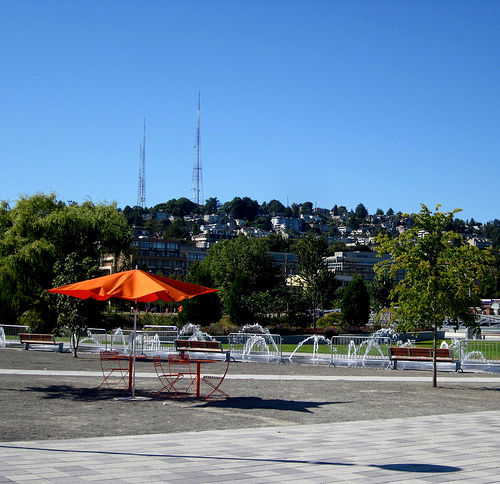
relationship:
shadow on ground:
[2, 444, 462, 474] [0, 349, 498, 481]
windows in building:
[133, 237, 183, 249] [122, 235, 188, 282]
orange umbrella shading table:
[46, 264, 219, 393] [99, 349, 230, 404]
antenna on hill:
[190, 85, 205, 210] [2, 190, 497, 342]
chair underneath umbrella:
[98, 348, 132, 392] [47, 271, 220, 353]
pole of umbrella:
[128, 302, 138, 399] [46, 268, 213, 303]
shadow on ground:
[190, 396, 354, 414] [0, 349, 498, 481]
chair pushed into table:
[83, 316, 132, 393] [78, 338, 287, 404]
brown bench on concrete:
[169, 330, 234, 365] [235, 357, 267, 379]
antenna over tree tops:
[190, 89, 205, 210] [38, 181, 260, 262]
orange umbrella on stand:
[46, 264, 219, 402] [118, 350, 153, 407]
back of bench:
[383, 335, 487, 365] [372, 329, 497, 377]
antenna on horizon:
[190, 89, 205, 210] [23, 182, 462, 230]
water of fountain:
[260, 330, 371, 370] [95, 318, 438, 377]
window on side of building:
[153, 241, 162, 249] [125, 234, 183, 269]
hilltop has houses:
[81, 183, 451, 313] [121, 203, 496, 251]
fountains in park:
[232, 307, 446, 384] [5, 189, 479, 484]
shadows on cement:
[1, 437, 467, 479] [9, 332, 485, 477]